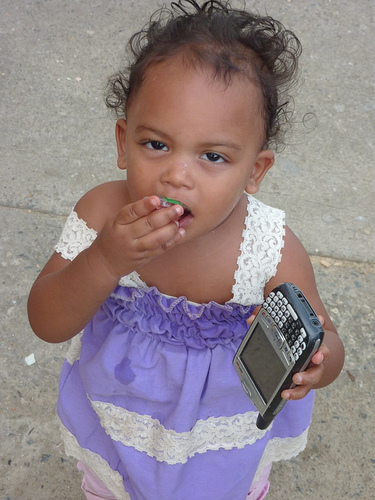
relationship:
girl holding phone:
[23, 1, 349, 500] [227, 276, 328, 432]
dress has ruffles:
[48, 187, 320, 496] [103, 285, 257, 360]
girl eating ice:
[23, 1, 349, 500] [152, 196, 174, 212]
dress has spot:
[48, 187, 320, 496] [110, 352, 146, 390]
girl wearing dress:
[23, 1, 349, 500] [48, 187, 320, 496]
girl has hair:
[23, 1, 349, 500] [96, 2, 322, 162]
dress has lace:
[48, 187, 320, 496] [224, 191, 291, 312]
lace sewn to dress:
[224, 191, 291, 312] [48, 187, 320, 496]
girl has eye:
[23, 1, 349, 500] [198, 144, 234, 173]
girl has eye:
[23, 1, 349, 500] [131, 131, 177, 163]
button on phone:
[284, 301, 300, 324] [227, 276, 328, 432]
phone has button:
[227, 276, 328, 432] [284, 301, 300, 324]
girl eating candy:
[23, 1, 349, 500] [156, 196, 184, 215]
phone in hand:
[227, 276, 328, 432] [244, 297, 327, 410]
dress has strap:
[48, 187, 320, 496] [48, 200, 149, 299]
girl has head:
[23, 1, 349, 500] [103, 0, 322, 249]